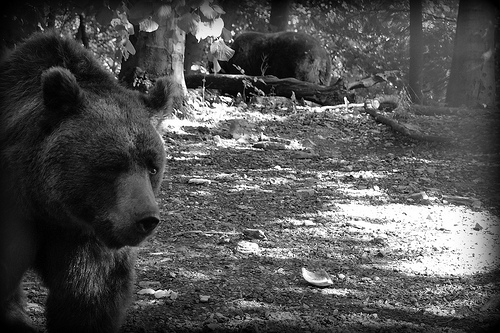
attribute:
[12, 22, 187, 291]
bear — foraging, walking, brown, furry, looking, large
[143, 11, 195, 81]
trees — thick, large, fallen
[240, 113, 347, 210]
ground — dirt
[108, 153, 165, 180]
eyes — open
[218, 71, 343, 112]
log — fallen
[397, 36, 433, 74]
trunk — large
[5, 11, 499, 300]
picture — black, white